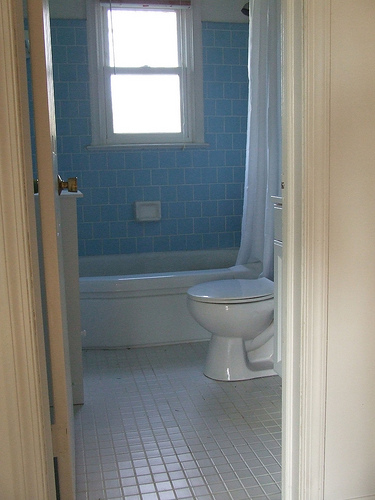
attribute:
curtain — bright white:
[242, 0, 275, 247]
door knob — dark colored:
[55, 173, 80, 196]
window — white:
[99, 3, 184, 135]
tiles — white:
[78, 343, 278, 498]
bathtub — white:
[78, 246, 238, 353]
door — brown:
[28, 1, 76, 499]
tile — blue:
[208, 47, 221, 62]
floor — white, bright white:
[73, 341, 284, 495]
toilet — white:
[187, 267, 274, 384]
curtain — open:
[246, 3, 282, 293]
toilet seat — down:
[192, 273, 284, 319]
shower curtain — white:
[232, 0, 279, 274]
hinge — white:
[44, 418, 75, 463]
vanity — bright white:
[248, 190, 311, 393]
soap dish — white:
[123, 191, 174, 229]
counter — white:
[24, 178, 88, 207]